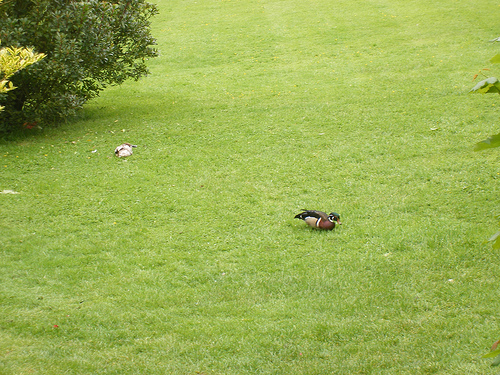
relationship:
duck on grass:
[309, 205, 341, 234] [325, 114, 366, 162]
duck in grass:
[309, 205, 341, 234] [325, 114, 366, 162]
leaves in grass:
[92, 117, 113, 139] [325, 114, 366, 162]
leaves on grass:
[92, 117, 113, 139] [325, 114, 366, 162]